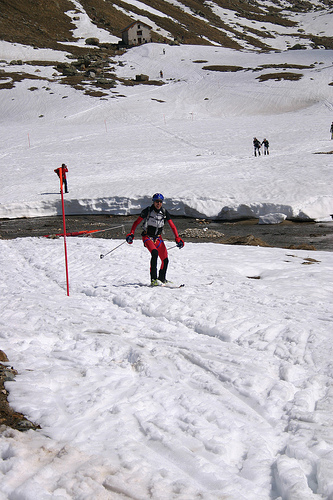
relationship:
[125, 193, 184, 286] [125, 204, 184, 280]
man wearing clothing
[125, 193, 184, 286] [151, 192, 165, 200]
man wearing blue helmet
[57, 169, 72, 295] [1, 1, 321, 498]
pole stuck in snow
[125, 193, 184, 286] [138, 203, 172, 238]
man wearing top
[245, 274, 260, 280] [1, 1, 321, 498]
spot melted in snow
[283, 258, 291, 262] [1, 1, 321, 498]
spot melted in snow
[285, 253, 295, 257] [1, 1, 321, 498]
spot melted in snow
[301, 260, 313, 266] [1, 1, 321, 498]
spot melted in snow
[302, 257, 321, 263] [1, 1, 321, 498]
spot melted in snow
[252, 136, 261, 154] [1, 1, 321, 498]
person walking in snow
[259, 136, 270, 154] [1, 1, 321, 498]
person walking in snow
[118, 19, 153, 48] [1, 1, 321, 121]
building standing on hill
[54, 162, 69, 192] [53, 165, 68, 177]
guy wearing red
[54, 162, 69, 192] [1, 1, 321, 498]
guy walking in snow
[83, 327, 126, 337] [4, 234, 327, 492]
ski track crisscrossing snow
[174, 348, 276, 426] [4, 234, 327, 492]
ski track crisscrossing snow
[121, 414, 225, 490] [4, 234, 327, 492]
ski track crisscrossing snow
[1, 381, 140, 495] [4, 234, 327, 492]
ski track crisscrossing snow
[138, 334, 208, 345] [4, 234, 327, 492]
ski track crisscrossing snow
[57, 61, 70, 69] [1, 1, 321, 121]
boulder lying on hill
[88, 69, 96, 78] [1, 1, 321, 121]
boulder lying on hill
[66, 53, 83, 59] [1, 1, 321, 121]
boulder lying on hill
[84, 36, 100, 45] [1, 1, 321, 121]
boulder lying on hill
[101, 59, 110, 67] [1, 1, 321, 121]
boulder lying on hill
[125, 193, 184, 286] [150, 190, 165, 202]
man wearing a blue helmet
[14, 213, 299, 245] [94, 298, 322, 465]
stream running through snow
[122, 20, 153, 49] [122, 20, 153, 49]
building to left of building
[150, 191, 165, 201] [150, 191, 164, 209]
blue helmet on skier's head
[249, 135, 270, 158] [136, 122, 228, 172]
two people walking in snow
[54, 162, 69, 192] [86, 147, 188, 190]
guy walking on snow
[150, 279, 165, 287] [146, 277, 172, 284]
person's feet on person's feet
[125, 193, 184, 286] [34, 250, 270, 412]
man on snow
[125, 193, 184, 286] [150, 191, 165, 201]
man wearing a blue helmet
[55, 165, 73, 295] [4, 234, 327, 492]
pole in snow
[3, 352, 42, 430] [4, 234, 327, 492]
rocks in snow